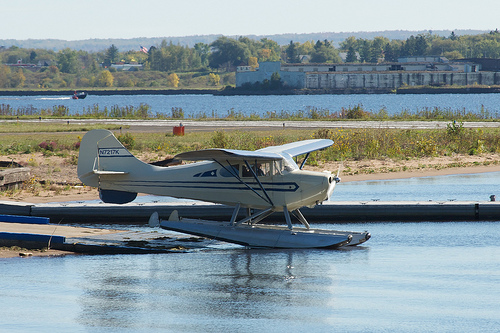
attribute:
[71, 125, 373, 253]
plane — small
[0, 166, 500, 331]
water — cool, rippling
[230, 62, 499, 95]
house — white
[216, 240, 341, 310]
shade — part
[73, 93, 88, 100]
boat — blue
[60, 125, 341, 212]
airplane — white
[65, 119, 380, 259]
air plane — white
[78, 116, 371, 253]
airplane — white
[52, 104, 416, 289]
plane — sea-faring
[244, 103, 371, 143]
road — small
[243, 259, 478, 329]
water — part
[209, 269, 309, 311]
shade — part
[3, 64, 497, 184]
grass — green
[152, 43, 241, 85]
tree — large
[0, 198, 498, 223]
bridge — part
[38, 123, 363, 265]
plane — part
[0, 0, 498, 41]
sky — clear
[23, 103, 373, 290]
plane — white